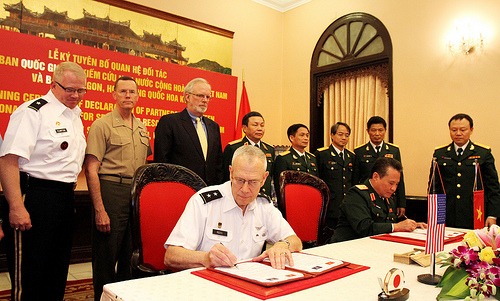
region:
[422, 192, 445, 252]
A mini US Flag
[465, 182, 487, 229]
A mini Chinese Flag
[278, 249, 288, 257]
A man's ring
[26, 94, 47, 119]
A american man's one star patch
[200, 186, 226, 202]
A american man's two star patch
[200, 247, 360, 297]
The book of papers being signed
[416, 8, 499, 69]
A bright, hanging wall light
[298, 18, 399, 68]
A set of wall mirrors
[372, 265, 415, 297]
A small glass ornament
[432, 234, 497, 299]
A set of vivid flowers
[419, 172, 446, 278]
American flag on the table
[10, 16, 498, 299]
Diplomates in the room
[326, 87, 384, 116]
Beige curtain on the door opening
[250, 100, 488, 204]
Military officials in the room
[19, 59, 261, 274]
American diplomats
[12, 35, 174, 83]
Red sign with writings in foreign language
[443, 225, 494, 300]
Beautiful flowers on the table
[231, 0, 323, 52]
Beige walls and white ceiling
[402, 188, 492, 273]
Two flags on the table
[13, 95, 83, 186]
White army uniform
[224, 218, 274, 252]
the shirt is white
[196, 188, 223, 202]
the patch has two stars on it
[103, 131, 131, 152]
the shirt is tan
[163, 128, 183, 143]
the jacket is black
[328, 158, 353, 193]
the jacket is green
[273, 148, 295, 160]
the patch is yellow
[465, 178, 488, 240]
the flag is red and yellow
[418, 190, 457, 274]
the flag is red white and blue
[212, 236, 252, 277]
the man is writing with a pen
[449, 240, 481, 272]
the flower is pink and white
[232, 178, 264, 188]
An old man's glasses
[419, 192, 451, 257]
A miniature US Flag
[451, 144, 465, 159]
A man's black tie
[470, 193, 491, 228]
A minaiture Chinese flag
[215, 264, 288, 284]
A group of official papers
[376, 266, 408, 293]
A glass ornament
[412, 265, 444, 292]
A small brown stand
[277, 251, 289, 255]
A man's ring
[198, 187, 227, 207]
A two star patch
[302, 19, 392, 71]
The Top of a glass window design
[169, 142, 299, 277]
this is a person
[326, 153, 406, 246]
this is a person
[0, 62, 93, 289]
this is a person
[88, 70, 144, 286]
this is a person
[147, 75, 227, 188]
this is a person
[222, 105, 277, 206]
this is a person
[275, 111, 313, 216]
this is a person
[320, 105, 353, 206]
this is a person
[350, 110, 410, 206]
this is a person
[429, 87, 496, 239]
this is a person